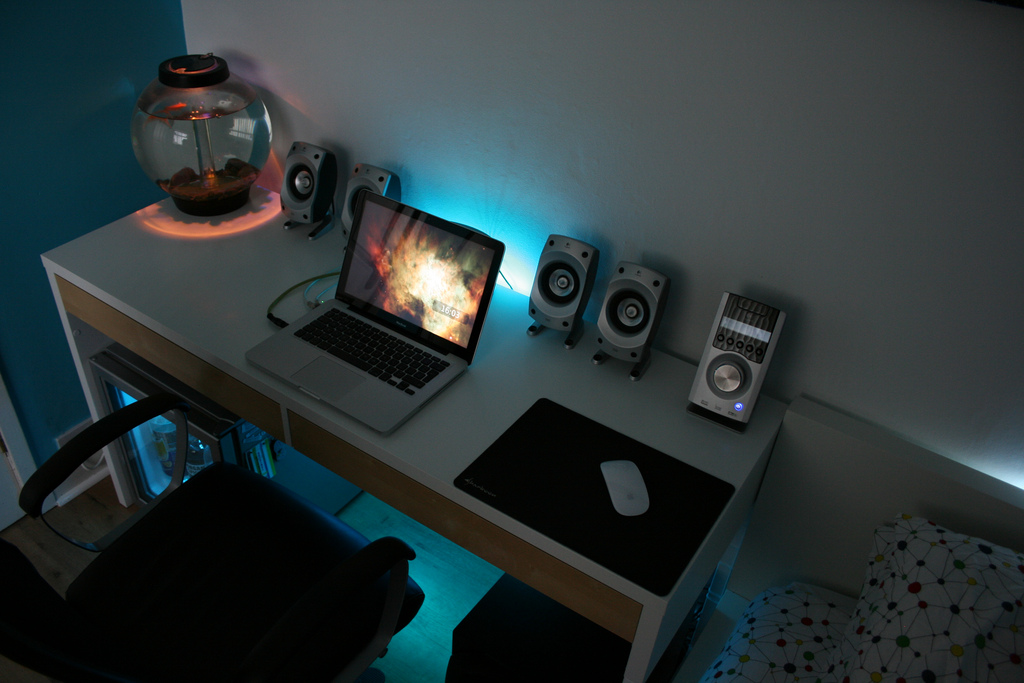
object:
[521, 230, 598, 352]
speaker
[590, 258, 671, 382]
speakers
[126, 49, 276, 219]
aquarium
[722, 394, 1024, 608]
frame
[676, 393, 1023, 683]
bed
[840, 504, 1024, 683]
pillow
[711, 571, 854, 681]
mattress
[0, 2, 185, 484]
wall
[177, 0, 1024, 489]
wall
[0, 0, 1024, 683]
bedroom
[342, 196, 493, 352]
screensaver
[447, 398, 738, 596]
mousepad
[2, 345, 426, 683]
office chair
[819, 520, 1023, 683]
furniture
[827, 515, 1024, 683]
pillow case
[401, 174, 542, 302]
glow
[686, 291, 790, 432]
music player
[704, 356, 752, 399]
dial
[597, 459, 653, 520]
mouse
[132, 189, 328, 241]
glow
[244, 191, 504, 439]
laptop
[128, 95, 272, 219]
water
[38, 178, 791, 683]
desk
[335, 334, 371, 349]
keys